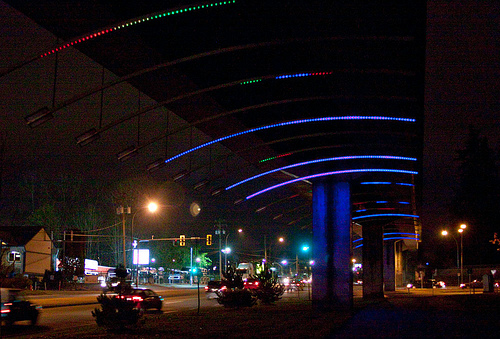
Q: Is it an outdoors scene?
A: Yes, it is outdoors.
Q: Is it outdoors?
A: Yes, it is outdoors.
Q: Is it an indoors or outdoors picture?
A: It is outdoors.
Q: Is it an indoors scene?
A: No, it is outdoors.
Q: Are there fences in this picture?
A: No, there are no fences.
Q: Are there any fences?
A: No, there are no fences.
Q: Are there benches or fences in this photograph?
A: No, there are no fences or benches.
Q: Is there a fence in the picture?
A: No, there are no fences.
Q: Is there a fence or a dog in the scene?
A: No, there are no fences or dogs.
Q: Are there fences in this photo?
A: No, there are no fences.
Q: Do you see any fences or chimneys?
A: No, there are no fences or chimneys.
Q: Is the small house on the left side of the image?
A: Yes, the house is on the left of the image.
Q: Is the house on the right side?
A: No, the house is on the left of the image.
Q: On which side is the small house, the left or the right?
A: The house is on the left of the image.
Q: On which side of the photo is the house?
A: The house is on the left of the image.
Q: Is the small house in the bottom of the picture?
A: Yes, the house is in the bottom of the image.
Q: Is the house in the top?
A: No, the house is in the bottom of the image.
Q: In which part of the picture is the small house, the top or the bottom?
A: The house is in the bottom of the image.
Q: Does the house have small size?
A: Yes, the house is small.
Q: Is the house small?
A: Yes, the house is small.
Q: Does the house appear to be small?
A: Yes, the house is small.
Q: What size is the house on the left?
A: The house is small.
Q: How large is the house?
A: The house is small.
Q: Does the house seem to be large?
A: No, the house is small.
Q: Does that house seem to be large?
A: No, the house is small.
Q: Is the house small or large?
A: The house is small.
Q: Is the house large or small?
A: The house is small.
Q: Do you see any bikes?
A: No, there are no bikes.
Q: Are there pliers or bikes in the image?
A: No, there are no bikes or pliers.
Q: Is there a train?
A: No, there are no trains.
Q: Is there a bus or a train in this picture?
A: No, there are no trains or buses.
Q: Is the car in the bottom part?
A: Yes, the car is in the bottom of the image.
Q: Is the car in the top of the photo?
A: No, the car is in the bottom of the image.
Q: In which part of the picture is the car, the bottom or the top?
A: The car is in the bottom of the image.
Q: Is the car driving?
A: Yes, the car is driving.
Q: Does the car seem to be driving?
A: Yes, the car is driving.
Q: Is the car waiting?
A: No, the car is driving.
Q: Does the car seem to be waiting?
A: No, the car is driving.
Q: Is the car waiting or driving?
A: The car is driving.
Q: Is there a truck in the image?
A: No, there are no trucks.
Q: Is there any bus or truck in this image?
A: No, there are no trucks or buses.